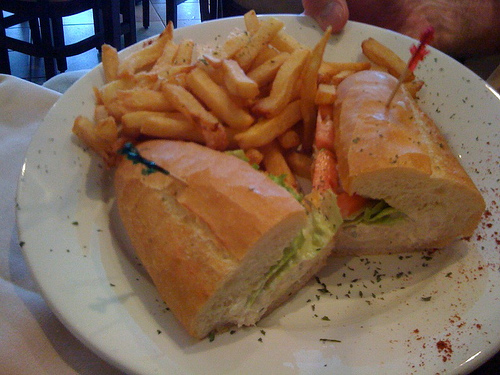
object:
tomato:
[307, 99, 365, 215]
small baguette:
[85, 46, 498, 341]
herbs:
[316, 248, 441, 327]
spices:
[442, 82, 495, 157]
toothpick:
[384, 22, 444, 120]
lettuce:
[243, 142, 409, 291]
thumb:
[300, 0, 351, 37]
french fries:
[75, 10, 436, 182]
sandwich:
[116, 117, 337, 330]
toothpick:
[114, 138, 171, 177]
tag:
[404, 22, 428, 70]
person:
[302, 0, 351, 35]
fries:
[97, 42, 120, 80]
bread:
[115, 137, 340, 339]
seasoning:
[272, 212, 499, 362]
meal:
[114, 68, 465, 303]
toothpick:
[393, 51, 423, 90]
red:
[302, 103, 331, 220]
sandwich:
[309, 67, 487, 261]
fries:
[161, 83, 228, 149]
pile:
[72, 99, 244, 159]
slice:
[315, 100, 345, 205]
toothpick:
[392, 99, 418, 146]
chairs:
[1, 50, 71, 83]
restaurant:
[6, 51, 75, 186]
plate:
[130, 260, 480, 375]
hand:
[312, 18, 348, 36]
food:
[112, 129, 339, 341]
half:
[270, 152, 405, 260]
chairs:
[0, 3, 118, 76]